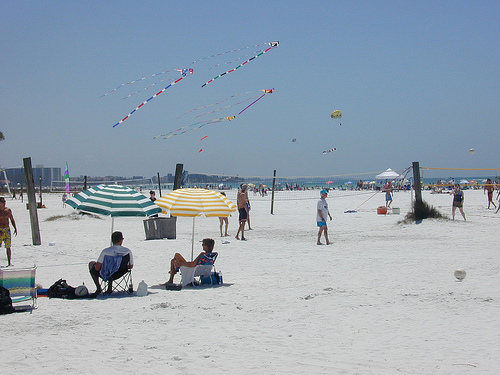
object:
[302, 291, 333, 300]
tracks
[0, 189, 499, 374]
sand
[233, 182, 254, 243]
man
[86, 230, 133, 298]
people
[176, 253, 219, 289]
chair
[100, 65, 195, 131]
skit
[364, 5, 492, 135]
sky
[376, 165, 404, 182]
umbrella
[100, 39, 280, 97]
kite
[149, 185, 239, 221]
umbrella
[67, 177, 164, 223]
umbrella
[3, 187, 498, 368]
beach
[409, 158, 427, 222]
post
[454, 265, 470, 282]
ball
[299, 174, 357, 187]
ocean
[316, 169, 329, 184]
water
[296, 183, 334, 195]
edge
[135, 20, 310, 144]
air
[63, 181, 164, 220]
green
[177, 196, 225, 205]
white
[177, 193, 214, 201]
yellow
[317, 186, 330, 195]
hat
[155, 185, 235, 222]
stripes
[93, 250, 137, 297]
couple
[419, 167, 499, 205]
net